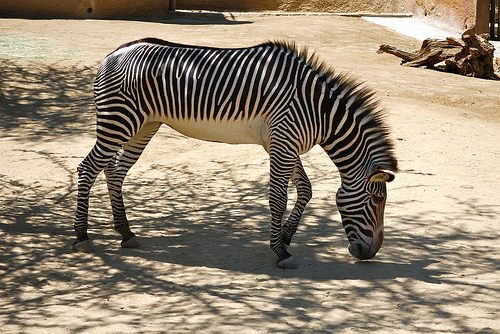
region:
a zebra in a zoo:
[41, 20, 425, 291]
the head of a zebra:
[332, 160, 397, 268]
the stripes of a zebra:
[141, 56, 306, 110]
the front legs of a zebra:
[256, 143, 321, 269]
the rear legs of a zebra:
[65, 128, 164, 263]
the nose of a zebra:
[343, 217, 385, 263]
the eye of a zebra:
[369, 189, 386, 204]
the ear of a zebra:
[366, 164, 397, 185]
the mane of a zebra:
[336, 56, 415, 155]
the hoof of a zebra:
[275, 252, 299, 269]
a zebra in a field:
[73, 34, 465, 279]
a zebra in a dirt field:
[64, 1, 499, 333]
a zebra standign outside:
[49, 41, 454, 325]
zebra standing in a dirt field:
[22, 21, 437, 329]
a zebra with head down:
[32, 13, 398, 333]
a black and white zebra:
[84, 16, 447, 331]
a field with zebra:
[59, 34, 476, 332]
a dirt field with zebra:
[52, 16, 447, 322]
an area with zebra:
[30, 26, 485, 326]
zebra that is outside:
[46, 39, 436, 311]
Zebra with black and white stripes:
[67, 37, 410, 272]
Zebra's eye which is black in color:
[369, 193, 386, 203]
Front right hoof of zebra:
[276, 248, 298, 271]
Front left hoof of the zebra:
[276, 226, 294, 248]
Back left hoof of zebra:
[118, 232, 144, 251]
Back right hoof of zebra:
[67, 236, 97, 253]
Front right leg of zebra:
[264, 143, 295, 259]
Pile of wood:
[379, 23, 491, 81]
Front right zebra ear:
[370, 169, 393, 186]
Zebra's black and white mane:
[270, 36, 392, 170]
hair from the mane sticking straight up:
[356, 86, 397, 160]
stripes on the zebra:
[159, 53, 274, 83]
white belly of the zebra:
[183, 122, 244, 141]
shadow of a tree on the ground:
[43, 238, 165, 314]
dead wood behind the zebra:
[393, 17, 485, 82]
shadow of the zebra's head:
[319, 257, 445, 287]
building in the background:
[14, 3, 189, 20]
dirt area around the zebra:
[418, 80, 488, 285]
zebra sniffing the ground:
[66, 17, 426, 292]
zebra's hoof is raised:
[283, 195, 316, 255]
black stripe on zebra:
[341, 218, 375, 235]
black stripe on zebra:
[340, 208, 366, 225]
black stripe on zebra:
[340, 191, 384, 220]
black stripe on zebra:
[341, 172, 369, 192]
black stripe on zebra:
[335, 123, 366, 171]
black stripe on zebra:
[318, 85, 351, 148]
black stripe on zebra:
[307, 59, 325, 145]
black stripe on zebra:
[292, 52, 312, 138]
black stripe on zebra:
[248, 32, 268, 128]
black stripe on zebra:
[208, 39, 237, 129]